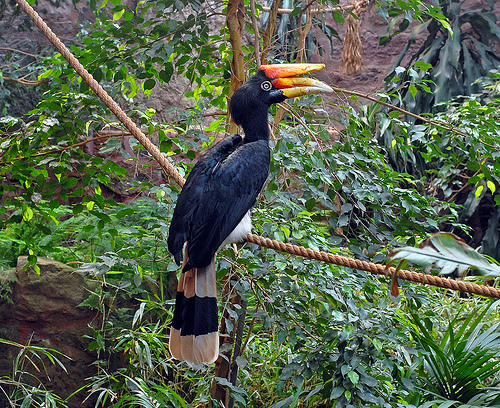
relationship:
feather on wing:
[221, 172, 230, 184] [181, 139, 271, 274]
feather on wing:
[221, 186, 230, 199] [181, 139, 271, 274]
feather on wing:
[207, 197, 215, 212] [181, 139, 271, 274]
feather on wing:
[214, 212, 222, 227] [181, 139, 271, 274]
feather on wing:
[216, 229, 224, 236] [181, 139, 271, 274]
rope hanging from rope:
[15, 3, 186, 190] [245, 232, 497, 301]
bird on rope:
[166, 63, 337, 367] [240, 234, 350, 271]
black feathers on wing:
[211, 199, 229, 226] [181, 139, 271, 274]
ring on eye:
[258, 77, 275, 93] [263, 83, 269, 88]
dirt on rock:
[2, 0, 457, 250] [3, 250, 129, 387]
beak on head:
[258, 52, 340, 101] [220, 50, 338, 135]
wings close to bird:
[165, 131, 272, 273] [169, 63, 329, 358]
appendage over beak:
[255, 57, 327, 77] [268, 75, 332, 100]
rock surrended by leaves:
[1, 242, 115, 400] [18, 82, 116, 281]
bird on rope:
[169, 63, 329, 358] [16, 0, 500, 300]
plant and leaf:
[426, 109, 482, 189] [444, 309, 462, 347]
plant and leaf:
[412, 306, 489, 400] [444, 309, 462, 347]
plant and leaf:
[273, 328, 390, 406] [127, 328, 157, 373]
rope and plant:
[16, 0, 500, 300] [426, 109, 482, 189]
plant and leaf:
[326, 167, 401, 248] [10, 195, 40, 227]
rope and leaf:
[16, 0, 500, 300] [444, 309, 462, 347]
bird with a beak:
[169, 63, 329, 358] [259, 60, 336, 96]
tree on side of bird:
[188, 3, 442, 401] [169, 63, 329, 358]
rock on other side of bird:
[11, 251, 104, 326] [149, 35, 363, 366]